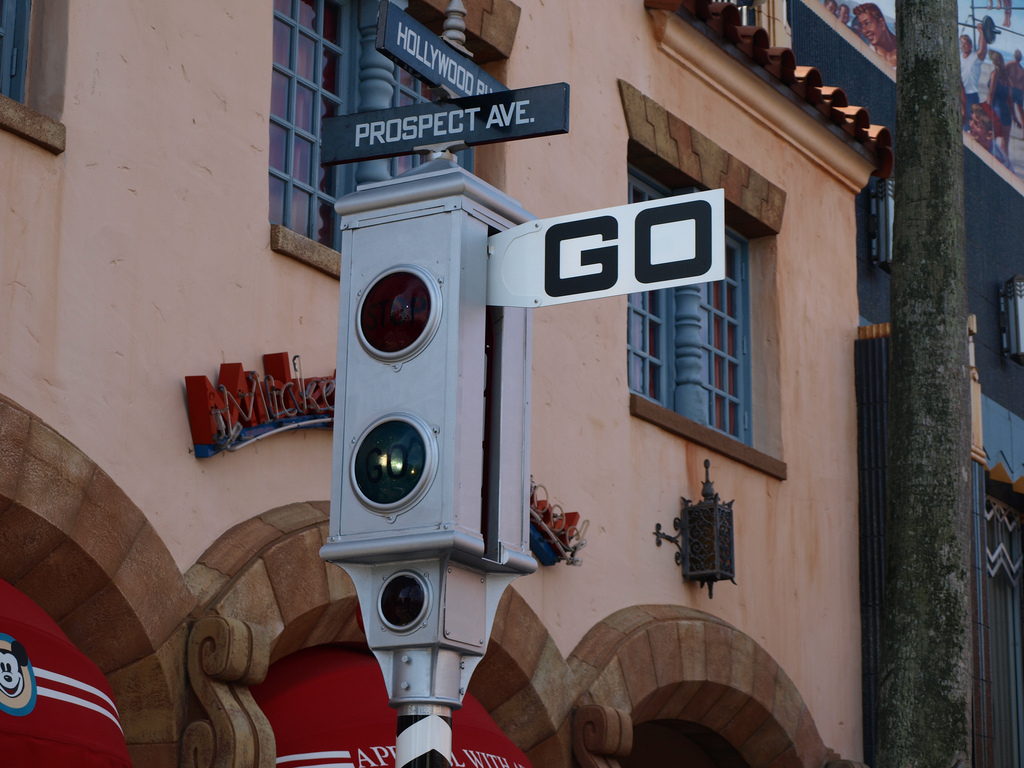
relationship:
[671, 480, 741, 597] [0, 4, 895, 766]
lamp on building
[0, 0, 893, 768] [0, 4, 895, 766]
building on building